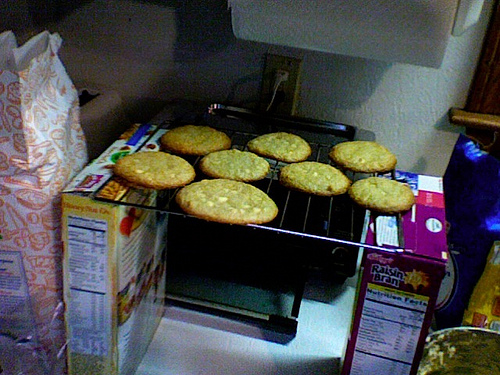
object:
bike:
[27, 4, 29, 6]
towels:
[228, 0, 444, 68]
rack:
[92, 121, 402, 251]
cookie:
[178, 175, 280, 226]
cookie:
[281, 160, 352, 199]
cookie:
[330, 139, 395, 173]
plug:
[264, 70, 289, 115]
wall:
[0, 3, 492, 173]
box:
[341, 170, 444, 373]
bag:
[434, 132, 499, 329]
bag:
[0, 30, 90, 374]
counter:
[126, 270, 361, 374]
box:
[62, 120, 170, 373]